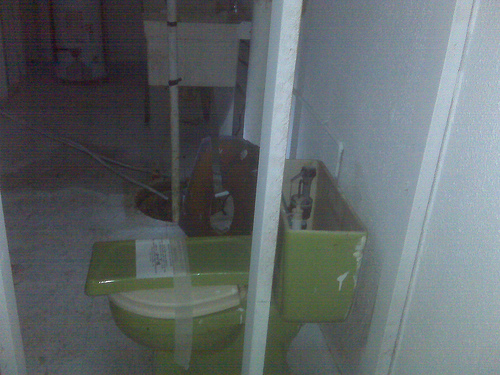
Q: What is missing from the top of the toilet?
A: The lid.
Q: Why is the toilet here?
A: It's being installed.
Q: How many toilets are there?
A: One.